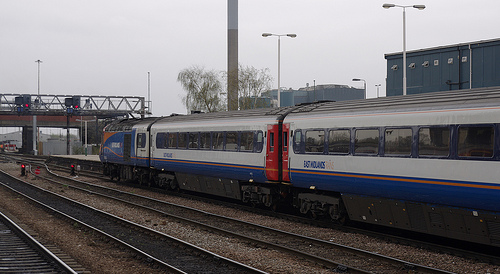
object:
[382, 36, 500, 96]
building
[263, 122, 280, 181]
doors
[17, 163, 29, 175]
train signal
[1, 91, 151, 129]
bridge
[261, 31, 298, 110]
tall/white lamp-posts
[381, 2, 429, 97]
tall/white lamp-posts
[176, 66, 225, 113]
tree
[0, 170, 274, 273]
tracks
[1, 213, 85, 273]
tracks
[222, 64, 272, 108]
tree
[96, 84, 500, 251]
train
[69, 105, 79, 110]
lights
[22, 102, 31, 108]
lights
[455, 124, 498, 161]
windows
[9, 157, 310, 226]
railroad tracks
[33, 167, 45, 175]
sign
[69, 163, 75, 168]
light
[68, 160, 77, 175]
post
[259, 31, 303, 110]
lamp posts